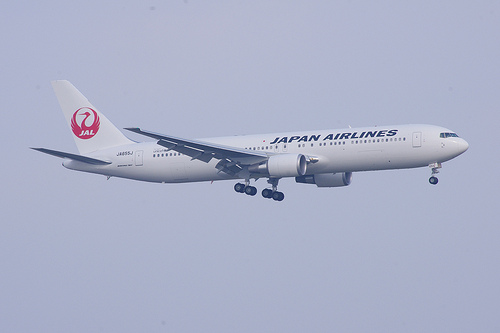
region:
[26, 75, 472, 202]
A plane in the air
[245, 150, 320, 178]
The right jet engine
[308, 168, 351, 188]
The left jet engine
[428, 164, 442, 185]
The front landing gear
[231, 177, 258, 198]
The rear right landing gear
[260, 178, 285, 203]
The left rear landing gear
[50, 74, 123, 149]
The vertical stabilizer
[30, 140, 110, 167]
The horizontal stabilizer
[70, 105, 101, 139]
The airline logo on the tail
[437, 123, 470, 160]
The cockpit of the plane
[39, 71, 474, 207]
white airplane in the sky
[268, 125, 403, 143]
japan airlines written in black on airplane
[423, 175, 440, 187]
front wheels of airplane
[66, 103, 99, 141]
red logo on white airplane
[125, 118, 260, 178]
wing of white airplane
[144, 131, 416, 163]
line of windows on side of plane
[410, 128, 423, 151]
door near cockpit of plane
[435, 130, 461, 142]
windows on front of plane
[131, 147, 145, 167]
door on backend of plane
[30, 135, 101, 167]
wing on tail of plane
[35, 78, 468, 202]
airplane from Japan flying through the air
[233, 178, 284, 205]
under wing landing gear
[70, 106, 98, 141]
Japan Airlines logo on the tail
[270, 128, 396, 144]
Blue lettering on the side of the plane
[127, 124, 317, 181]
Plane's right wing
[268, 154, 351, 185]
Two jet engines on the plane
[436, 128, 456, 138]
The airplane's cockpit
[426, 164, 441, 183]
The airplane's front landing gear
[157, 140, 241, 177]
Wing flaps on the right wing are down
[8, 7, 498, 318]
Sunny and clear day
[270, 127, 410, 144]
the words are black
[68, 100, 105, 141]
the emblem is red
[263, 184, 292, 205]
the tires are down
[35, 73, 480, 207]
the plane is flying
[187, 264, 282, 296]
the sky looks hazy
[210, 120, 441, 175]
the plane is white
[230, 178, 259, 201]
the tires are black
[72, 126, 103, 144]
the letters are white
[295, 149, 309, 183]
the ring of the engine is silver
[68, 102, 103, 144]
the emblem looks like some sort of fowl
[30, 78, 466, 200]
a commercial passenger jet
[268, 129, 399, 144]
"Japan Airlines" written on a plane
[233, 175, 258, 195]
landing wheels on a plane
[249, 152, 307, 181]
an airplanes engine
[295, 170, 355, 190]
an airplanes engine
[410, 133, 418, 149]
a door on an airplane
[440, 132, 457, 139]
a window on the front of a plane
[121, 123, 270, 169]
a wing on an airplane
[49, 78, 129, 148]
a tail wing on an airplane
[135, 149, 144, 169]
a door on the rear of an airplan